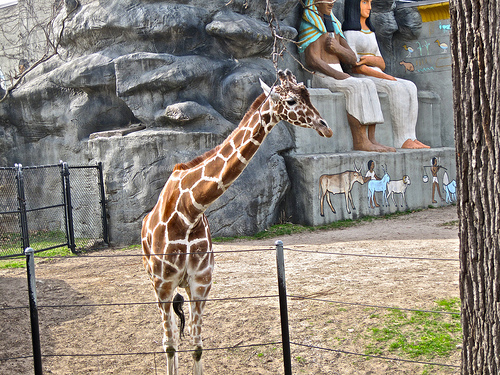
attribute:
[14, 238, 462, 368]
fence — wire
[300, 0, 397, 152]
statue — male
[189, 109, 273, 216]
neck — orange, white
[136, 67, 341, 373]
giraffe — spotted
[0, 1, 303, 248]
wall — grey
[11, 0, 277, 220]
wall — rocky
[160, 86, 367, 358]
giraffe — spotted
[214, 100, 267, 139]
mane — brown, long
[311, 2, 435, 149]
statue — man, woman, Egyptian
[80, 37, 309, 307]
giraffe — black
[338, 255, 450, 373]
grass — small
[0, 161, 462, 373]
fence — metal, wire, mesh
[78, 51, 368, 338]
giraffe — spotted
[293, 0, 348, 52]
head dress — blue, gold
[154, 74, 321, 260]
giraffe — spotted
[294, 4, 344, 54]
dress — blue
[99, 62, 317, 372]
giraffe — spotted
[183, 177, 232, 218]
spot — spotted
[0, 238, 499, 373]
fence — long, metal, wire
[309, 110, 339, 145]
nose — white, brown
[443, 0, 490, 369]
tree — large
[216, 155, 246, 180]
spot — brown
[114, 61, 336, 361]
giraffe — white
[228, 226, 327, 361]
pole — black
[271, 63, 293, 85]
horns — brown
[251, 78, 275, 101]
ear — white